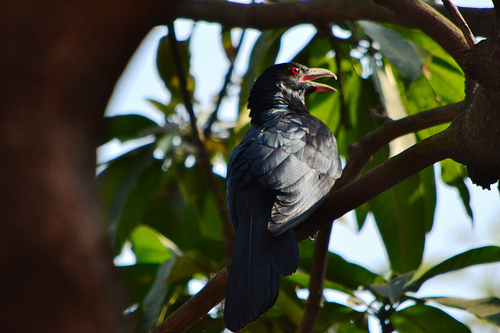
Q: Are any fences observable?
A: No, there are no fences.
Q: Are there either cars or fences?
A: No, there are no fences or cars.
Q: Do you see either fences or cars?
A: No, there are no fences or cars.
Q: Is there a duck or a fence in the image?
A: No, there are no fences or ducks.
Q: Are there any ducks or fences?
A: No, there are no fences or ducks.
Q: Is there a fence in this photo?
A: No, there are no fences.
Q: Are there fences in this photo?
A: No, there are no fences.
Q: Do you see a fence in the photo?
A: No, there are no fences.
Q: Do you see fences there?
A: No, there are no fences.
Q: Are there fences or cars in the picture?
A: No, there are no fences or cars.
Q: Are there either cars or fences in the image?
A: No, there are no fences or cars.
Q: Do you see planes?
A: No, there are no planes.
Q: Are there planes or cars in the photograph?
A: No, there are no planes or cars.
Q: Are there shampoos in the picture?
A: No, there are no shampoos.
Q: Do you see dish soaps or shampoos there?
A: No, there are no shampoos or dish soaps.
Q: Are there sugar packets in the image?
A: No, there are no sugar packets.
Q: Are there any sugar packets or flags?
A: No, there are no sugar packets or flags.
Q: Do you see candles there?
A: No, there are no candles.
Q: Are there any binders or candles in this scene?
A: No, there are no candles or binders.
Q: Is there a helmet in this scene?
A: No, there are no helmets.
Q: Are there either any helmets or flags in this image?
A: No, there are no helmets or flags.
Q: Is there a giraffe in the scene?
A: No, there are no giraffes.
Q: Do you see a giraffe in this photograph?
A: No, there are no giraffes.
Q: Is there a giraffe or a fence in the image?
A: No, there are no giraffes or fences.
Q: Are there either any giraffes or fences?
A: No, there are no giraffes or fences.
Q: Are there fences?
A: No, there are no fences.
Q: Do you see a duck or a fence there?
A: No, there are no fences or ducks.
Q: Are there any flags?
A: No, there are no flags.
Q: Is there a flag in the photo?
A: No, there are no flags.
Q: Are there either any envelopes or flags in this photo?
A: No, there are no flags or envelopes.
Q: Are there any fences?
A: No, there are no fences.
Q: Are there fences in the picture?
A: No, there are no fences.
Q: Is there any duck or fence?
A: No, there are no fences or ducks.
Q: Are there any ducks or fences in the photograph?
A: No, there are no fences or ducks.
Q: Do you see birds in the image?
A: Yes, there is a bird.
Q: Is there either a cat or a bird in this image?
A: Yes, there is a bird.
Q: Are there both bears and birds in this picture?
A: No, there is a bird but no bears.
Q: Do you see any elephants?
A: No, there are no elephants.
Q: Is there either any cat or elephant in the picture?
A: No, there are no elephants or cats.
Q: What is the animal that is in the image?
A: The animal is a bird.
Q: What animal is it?
A: The animal is a bird.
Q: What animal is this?
A: That is a bird.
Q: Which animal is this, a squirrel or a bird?
A: That is a bird.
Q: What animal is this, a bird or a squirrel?
A: This is a bird.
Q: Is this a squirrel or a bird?
A: This is a bird.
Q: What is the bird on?
A: The bird is on the branch.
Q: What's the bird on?
A: The bird is on the branch.